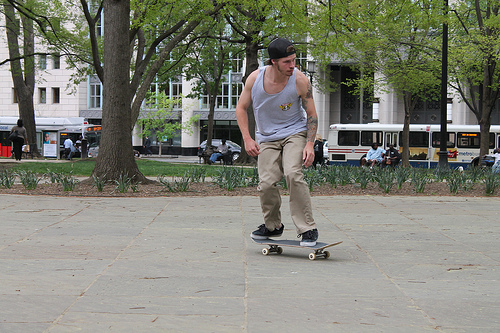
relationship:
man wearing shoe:
[234, 37, 319, 247] [295, 222, 327, 249]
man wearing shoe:
[234, 37, 319, 247] [245, 218, 288, 244]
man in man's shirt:
[235, 37, 324, 245] [248, 65, 308, 144]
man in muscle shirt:
[235, 37, 324, 245] [249, 65, 307, 138]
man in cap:
[235, 37, 324, 245] [267, 35, 299, 55]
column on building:
[167, 66, 203, 143] [107, 39, 240, 164]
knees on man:
[257, 163, 312, 190] [234, 37, 319, 247]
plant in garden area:
[156, 165, 204, 200] [338, 159, 493, 195]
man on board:
[62, 136, 74, 158] [251, 235, 344, 259]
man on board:
[235, 37, 324, 245] [251, 235, 344, 259]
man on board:
[361, 139, 385, 167] [251, 235, 344, 259]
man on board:
[234, 37, 319, 247] [251, 235, 344, 259]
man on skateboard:
[234, 37, 319, 247] [201, 182, 383, 292]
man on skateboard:
[234, 37, 319, 247] [242, 227, 347, 260]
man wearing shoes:
[234, 37, 319, 247] [251, 223, 322, 247]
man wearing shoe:
[234, 37, 319, 247] [295, 224, 320, 248]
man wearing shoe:
[234, 37, 319, 247] [249, 219, 291, 242]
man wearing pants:
[234, 37, 319, 247] [186, 136, 357, 242]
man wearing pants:
[234, 37, 319, 247] [253, 128, 319, 238]